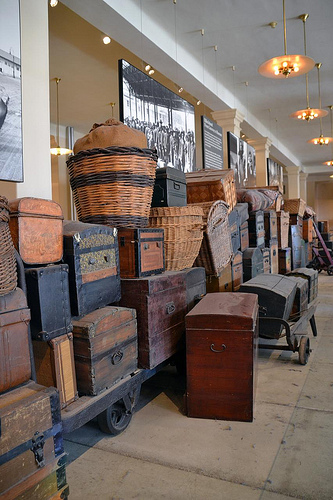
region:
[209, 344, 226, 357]
a handle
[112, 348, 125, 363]
a handle on the box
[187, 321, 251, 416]
the chest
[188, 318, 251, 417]
the chest is brown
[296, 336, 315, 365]
a wheel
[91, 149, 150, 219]
a basket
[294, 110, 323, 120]
a light in the ceiling is bright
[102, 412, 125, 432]
the wheel is black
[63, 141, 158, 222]
a tan and black basket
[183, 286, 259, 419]
a dark brown trunk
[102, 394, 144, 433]
a black cast iron wheel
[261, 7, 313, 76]
a light hanging from the ceiling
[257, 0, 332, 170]
a row of lights hanging from a ceiling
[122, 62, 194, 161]
a black and white picture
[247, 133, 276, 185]
a white colum on the wall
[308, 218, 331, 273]
a red dolly in the distance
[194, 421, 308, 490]
a concrete tan floor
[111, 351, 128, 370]
a black handle on a trunk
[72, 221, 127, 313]
hump back trunk in a pile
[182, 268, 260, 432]
wooden box in front of the pile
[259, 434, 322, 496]
lines on the pavement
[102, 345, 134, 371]
handle on a trunk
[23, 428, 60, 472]
clasp on a trunk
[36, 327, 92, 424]
suitcase in the pile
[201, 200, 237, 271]
wicker basket in a pile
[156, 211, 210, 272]
brown basket in a pile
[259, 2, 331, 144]
lights hanging from ceiling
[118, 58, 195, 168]
black and white photo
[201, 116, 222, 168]
white words on black surface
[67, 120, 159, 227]
bag in wicker basket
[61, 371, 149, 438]
wheel on bottom of cart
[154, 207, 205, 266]
handle on wicker basket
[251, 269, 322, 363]
three trunks on cart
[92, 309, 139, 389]
handle on wood trunk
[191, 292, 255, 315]
dust on trunk top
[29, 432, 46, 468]
latch on side of trunk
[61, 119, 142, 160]
burlap sack in basket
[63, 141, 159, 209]
brown and black basket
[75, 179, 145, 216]
brown middle of basket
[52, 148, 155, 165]
black top of basket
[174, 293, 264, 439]
brown wooden crate on ground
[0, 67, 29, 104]
picture on the wall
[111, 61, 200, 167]
picture on the wall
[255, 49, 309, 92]
light hanging from ceiling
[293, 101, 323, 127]
light hanging from ceiling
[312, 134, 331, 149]
light hanging from ceiling